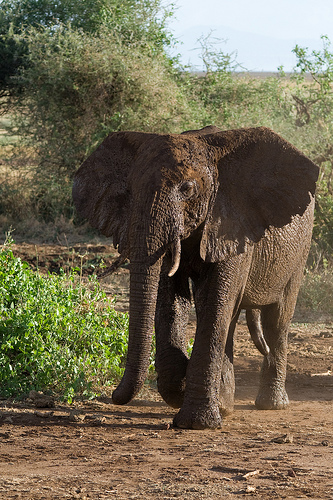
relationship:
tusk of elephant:
[166, 235, 182, 279] [63, 112, 325, 434]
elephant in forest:
[41, 115, 332, 438] [8, 4, 322, 307]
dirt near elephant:
[14, 308, 294, 498] [63, 112, 325, 434]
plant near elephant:
[0, 230, 130, 400] [63, 112, 325, 434]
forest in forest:
[0, 1, 331, 304] [8, 4, 322, 307]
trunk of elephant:
[110, 186, 178, 407] [63, 112, 325, 434]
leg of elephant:
[173, 264, 248, 430] [63, 112, 325, 434]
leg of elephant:
[155, 268, 195, 409] [63, 112, 325, 434]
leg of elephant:
[254, 275, 306, 410] [63, 112, 325, 434]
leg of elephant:
[218, 303, 242, 417] [63, 112, 325, 434]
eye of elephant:
[177, 178, 199, 198] [82, 127, 328, 459]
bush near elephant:
[1, 284, 105, 384] [63, 112, 325, 434]